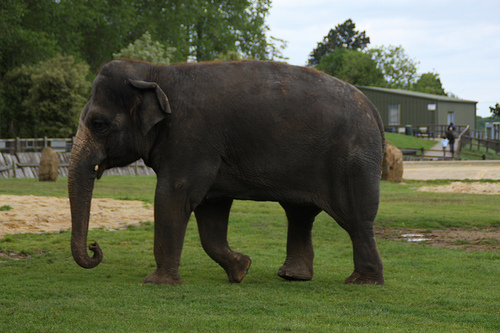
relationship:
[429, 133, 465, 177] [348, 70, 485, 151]
ramp to building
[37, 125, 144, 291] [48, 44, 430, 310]
trunk of elephant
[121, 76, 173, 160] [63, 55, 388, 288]
ear of elephant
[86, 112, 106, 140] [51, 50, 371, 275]
eye of elephant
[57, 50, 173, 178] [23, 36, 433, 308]
head of elephant